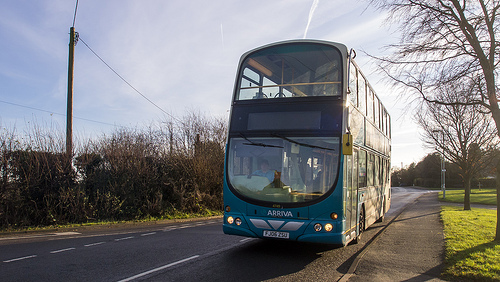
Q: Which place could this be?
A: It is a road.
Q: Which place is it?
A: It is a road.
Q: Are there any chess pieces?
A: No, there are no chess pieces.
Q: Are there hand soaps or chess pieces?
A: No, there are no chess pieces or hand soaps.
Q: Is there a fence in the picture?
A: No, there are no fences.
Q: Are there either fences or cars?
A: No, there are no fences or cars.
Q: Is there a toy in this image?
A: No, there are no toys.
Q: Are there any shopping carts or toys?
A: No, there are no toys or shopping carts.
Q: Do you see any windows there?
A: Yes, there is a window.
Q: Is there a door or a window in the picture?
A: Yes, there is a window.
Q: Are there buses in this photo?
A: Yes, there is a bus.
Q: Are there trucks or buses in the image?
A: Yes, there is a bus.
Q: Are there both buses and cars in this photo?
A: No, there is a bus but no cars.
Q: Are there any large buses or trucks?
A: Yes, there is a large bus.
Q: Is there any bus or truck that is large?
A: Yes, the bus is large.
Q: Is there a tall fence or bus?
A: Yes, there is a tall bus.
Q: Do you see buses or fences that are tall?
A: Yes, the bus is tall.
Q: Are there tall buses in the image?
A: Yes, there is a tall bus.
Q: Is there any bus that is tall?
A: Yes, there is a bus that is tall.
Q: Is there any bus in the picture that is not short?
A: Yes, there is a tall bus.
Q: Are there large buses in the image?
A: Yes, there is a large bus.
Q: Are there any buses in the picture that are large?
A: Yes, there is a bus that is large.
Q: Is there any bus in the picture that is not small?
A: Yes, there is a large bus.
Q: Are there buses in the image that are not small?
A: Yes, there is a large bus.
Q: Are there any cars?
A: No, there are no cars.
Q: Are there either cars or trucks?
A: No, there are no cars or trucks.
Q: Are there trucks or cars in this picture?
A: No, there are no cars or trucks.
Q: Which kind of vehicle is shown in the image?
A: The vehicle is a bus.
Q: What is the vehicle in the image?
A: The vehicle is a bus.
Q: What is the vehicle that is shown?
A: The vehicle is a bus.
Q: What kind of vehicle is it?
A: The vehicle is a bus.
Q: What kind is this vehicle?
A: This is a bus.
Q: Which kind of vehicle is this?
A: This is a bus.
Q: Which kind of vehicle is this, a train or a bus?
A: This is a bus.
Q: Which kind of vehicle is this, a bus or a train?
A: This is a bus.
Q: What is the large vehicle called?
A: The vehicle is a bus.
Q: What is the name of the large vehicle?
A: The vehicle is a bus.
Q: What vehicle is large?
A: The vehicle is a bus.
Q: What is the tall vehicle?
A: The vehicle is a bus.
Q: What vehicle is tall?
A: The vehicle is a bus.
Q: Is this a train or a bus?
A: This is a bus.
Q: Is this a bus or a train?
A: This is a bus.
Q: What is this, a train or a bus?
A: This is a bus.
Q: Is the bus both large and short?
A: No, the bus is large but tall.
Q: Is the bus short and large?
A: No, the bus is large but tall.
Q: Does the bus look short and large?
A: No, the bus is large but tall.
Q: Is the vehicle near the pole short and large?
A: No, the bus is large but tall.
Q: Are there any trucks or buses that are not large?
A: No, there is a bus but it is large.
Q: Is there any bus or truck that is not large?
A: No, there is a bus but it is large.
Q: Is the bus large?
A: Yes, the bus is large.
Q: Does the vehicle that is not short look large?
A: Yes, the bus is large.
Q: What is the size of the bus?
A: The bus is large.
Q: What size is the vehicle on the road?
A: The bus is large.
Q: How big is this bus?
A: The bus is large.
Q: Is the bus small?
A: No, the bus is large.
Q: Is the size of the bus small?
A: No, the bus is large.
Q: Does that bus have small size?
A: No, the bus is large.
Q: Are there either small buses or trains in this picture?
A: No, there is a bus but it is large.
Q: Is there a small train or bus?
A: No, there is a bus but it is large.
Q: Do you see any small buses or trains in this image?
A: No, there is a bus but it is large.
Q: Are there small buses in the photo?
A: No, there is a bus but it is large.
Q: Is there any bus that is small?
A: No, there is a bus but it is large.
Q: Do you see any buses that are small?
A: No, there is a bus but it is large.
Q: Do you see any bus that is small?
A: No, there is a bus but it is large.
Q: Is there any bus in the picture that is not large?
A: No, there is a bus but it is large.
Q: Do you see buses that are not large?
A: No, there is a bus but it is large.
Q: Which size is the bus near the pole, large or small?
A: The bus is large.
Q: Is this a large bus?
A: Yes, this is a large bus.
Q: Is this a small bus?
A: No, this is a large bus.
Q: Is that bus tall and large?
A: Yes, the bus is tall and large.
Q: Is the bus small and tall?
A: No, the bus is tall but large.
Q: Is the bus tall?
A: Yes, the bus is tall.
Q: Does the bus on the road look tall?
A: Yes, the bus is tall.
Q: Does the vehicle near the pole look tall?
A: Yes, the bus is tall.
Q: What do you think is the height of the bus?
A: The bus is tall.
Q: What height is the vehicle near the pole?
A: The bus is tall.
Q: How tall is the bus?
A: The bus is tall.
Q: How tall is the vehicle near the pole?
A: The bus is tall.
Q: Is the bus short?
A: No, the bus is tall.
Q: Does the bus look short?
A: No, the bus is tall.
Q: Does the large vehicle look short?
A: No, the bus is tall.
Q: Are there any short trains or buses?
A: No, there is a bus but it is tall.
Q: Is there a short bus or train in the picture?
A: No, there is a bus but it is tall.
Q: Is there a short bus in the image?
A: No, there is a bus but it is tall.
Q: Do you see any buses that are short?
A: No, there is a bus but it is tall.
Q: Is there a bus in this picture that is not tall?
A: No, there is a bus but it is tall.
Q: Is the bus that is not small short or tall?
A: The bus is tall.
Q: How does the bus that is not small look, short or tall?
A: The bus is tall.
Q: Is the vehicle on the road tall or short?
A: The bus is tall.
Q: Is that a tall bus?
A: Yes, that is a tall bus.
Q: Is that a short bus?
A: No, that is a tall bus.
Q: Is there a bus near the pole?
A: Yes, there is a bus near the pole.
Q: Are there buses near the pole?
A: Yes, there is a bus near the pole.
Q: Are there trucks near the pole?
A: No, there is a bus near the pole.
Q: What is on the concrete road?
A: The bus is on the road.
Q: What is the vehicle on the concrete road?
A: The vehicle is a bus.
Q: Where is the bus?
A: The bus is on the road.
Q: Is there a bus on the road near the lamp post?
A: Yes, there is a bus on the road.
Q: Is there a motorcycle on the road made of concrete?
A: No, there is a bus on the road.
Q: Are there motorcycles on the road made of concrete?
A: No, there is a bus on the road.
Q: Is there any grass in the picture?
A: Yes, there is grass.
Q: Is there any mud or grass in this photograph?
A: Yes, there is grass.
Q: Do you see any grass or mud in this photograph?
A: Yes, there is grass.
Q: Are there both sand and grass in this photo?
A: No, there is grass but no sand.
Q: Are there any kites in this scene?
A: No, there are no kites.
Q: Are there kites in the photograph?
A: No, there are no kites.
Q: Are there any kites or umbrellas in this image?
A: No, there are no kites or umbrellas.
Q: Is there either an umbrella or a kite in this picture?
A: No, there are no kites or umbrellas.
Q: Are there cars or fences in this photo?
A: No, there are no cars or fences.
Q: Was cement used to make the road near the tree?
A: Yes, the road is made of cement.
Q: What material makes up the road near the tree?
A: The road is made of concrete.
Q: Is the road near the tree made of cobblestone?
A: No, the road is made of concrete.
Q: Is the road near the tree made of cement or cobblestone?
A: The road is made of cement.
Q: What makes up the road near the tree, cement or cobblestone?
A: The road is made of cement.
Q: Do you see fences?
A: No, there are no fences.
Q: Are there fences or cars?
A: No, there are no fences or cars.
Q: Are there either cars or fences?
A: No, there are no fences or cars.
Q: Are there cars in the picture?
A: No, there are no cars.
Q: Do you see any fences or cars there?
A: No, there are no cars or fences.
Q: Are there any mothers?
A: No, there are no mothers.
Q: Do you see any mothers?
A: No, there are no mothers.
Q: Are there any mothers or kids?
A: No, there are no mothers or kids.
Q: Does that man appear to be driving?
A: Yes, the man is driving.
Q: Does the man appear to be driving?
A: Yes, the man is driving.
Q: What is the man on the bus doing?
A: The man is driving.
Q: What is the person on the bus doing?
A: The man is driving.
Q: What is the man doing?
A: The man is driving.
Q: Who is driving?
A: The man is driving.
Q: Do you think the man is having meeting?
A: No, the man is driving.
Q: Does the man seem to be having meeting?
A: No, the man is driving.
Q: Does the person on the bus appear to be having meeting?
A: No, the man is driving.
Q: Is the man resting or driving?
A: The man is driving.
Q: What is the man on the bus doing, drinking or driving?
A: The man is driving.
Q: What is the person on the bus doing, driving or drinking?
A: The man is driving.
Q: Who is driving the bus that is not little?
A: The man is driving the bus.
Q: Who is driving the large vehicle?
A: The man is driving the bus.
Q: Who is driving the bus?
A: The man is driving the bus.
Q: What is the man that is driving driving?
A: The man is driving the bus.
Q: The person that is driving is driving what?
A: The man is driving the bus.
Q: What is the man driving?
A: The man is driving the bus.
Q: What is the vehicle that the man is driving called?
A: The vehicle is a bus.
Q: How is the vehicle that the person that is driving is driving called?
A: The vehicle is a bus.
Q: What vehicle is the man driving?
A: The man is driving the bus.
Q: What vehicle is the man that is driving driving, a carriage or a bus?
A: The man is driving a bus.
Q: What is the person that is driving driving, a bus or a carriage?
A: The man is driving a bus.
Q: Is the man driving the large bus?
A: Yes, the man is driving the bus.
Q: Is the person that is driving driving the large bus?
A: Yes, the man is driving the bus.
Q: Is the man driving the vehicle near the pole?
A: Yes, the man is driving the bus.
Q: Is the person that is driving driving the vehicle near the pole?
A: Yes, the man is driving the bus.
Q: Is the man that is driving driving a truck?
A: No, the man is driving the bus.